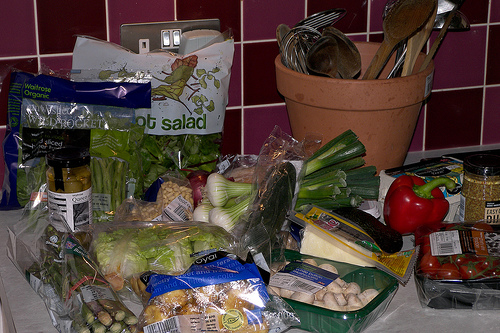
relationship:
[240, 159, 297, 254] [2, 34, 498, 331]
pickle of produce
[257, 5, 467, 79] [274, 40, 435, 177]
utensils in container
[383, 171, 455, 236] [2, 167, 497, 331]
pepper on counter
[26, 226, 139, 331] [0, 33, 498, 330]
asparagus on produce pile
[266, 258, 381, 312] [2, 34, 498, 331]
mushrooms on produce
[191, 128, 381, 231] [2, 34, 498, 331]
leeks on produce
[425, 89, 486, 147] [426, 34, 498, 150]
red square on wall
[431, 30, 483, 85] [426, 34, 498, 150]
red square on wall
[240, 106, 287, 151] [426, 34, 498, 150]
red square on wall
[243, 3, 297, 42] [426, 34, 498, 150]
red square on wall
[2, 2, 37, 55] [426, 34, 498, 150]
red square on wall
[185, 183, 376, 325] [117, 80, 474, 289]
mushrooms in container